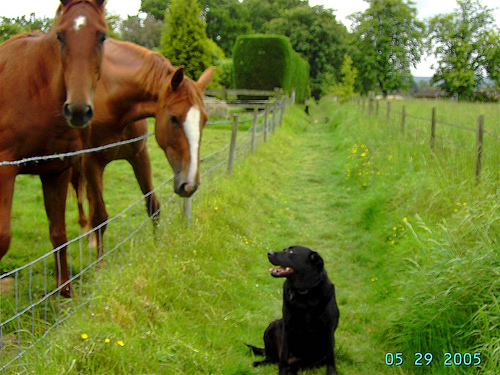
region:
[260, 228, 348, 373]
black dog in front of two horses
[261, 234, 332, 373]
black dog looking to the side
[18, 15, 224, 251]
There are two horses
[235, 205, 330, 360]
The dog is sitting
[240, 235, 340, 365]
The dog is black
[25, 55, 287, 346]
Grey wire fence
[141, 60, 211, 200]
The horse has a white blaze on its head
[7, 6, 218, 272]
The horses are chestnut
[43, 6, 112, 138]
The horse has a star on its head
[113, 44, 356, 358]
The horse is looking at the dog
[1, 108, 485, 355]
Long, green grassy fields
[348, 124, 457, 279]
Yellow flowers in the grass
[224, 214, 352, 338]
black dog is sitting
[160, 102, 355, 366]
black dog is sitting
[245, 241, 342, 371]
the dog on the grass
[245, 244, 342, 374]
the dog sitting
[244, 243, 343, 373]
the black dog sitting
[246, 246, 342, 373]
the dog looking at the horses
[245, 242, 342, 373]
the dog sitting with the mouth open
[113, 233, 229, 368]
the long grass near the horses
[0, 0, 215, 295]
the two brown horses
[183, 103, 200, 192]
the long white spot on the horses face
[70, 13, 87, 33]
the small white spot on the horses head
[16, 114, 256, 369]
the wired fence near the horse